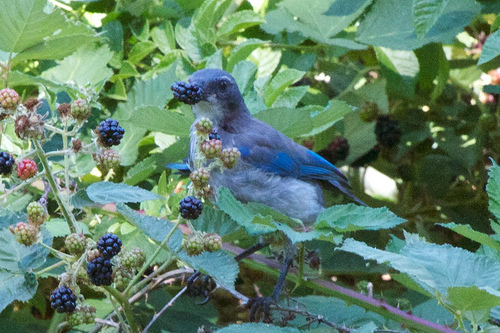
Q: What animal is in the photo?
A: A bird.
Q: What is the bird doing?
A: Eating fruit.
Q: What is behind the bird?
A: Leaves.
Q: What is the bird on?
A: A tree.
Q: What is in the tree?
A: Leaves.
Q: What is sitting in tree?
A: Bird.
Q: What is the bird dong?
A: Eating.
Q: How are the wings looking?
A: Blue.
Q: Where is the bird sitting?
A: Tree.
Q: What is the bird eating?
A: Berry.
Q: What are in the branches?
A: Thorns.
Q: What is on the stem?
A: Blackberry.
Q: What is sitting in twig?
A: Bird.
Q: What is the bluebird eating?
A: Blackberries.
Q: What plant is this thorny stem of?
A: A blackberry plant.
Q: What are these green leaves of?
A: A blackberry bush.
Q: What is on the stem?
A: A pair of black birds legs.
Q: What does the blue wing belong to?
A: A bird.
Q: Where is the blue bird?
A: In the leaves.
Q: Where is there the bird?
A: On a tree.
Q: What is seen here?
A: Trees in the photo.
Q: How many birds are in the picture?
A: One.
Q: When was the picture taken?
A: During the day.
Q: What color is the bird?
A: Blue.